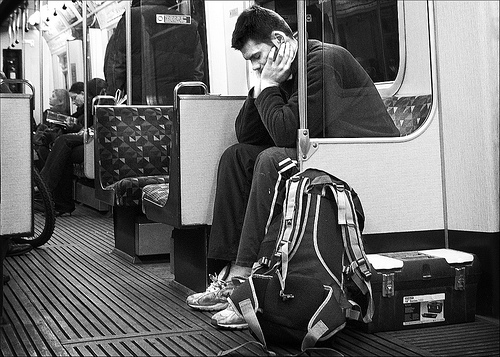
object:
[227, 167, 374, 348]
bag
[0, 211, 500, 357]
floor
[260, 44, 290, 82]
hand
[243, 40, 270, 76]
face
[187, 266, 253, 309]
feet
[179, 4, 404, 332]
man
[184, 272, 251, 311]
shoe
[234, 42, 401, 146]
shirt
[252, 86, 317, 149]
sleeve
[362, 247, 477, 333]
case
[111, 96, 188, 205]
seat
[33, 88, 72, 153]
people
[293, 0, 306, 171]
pole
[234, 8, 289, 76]
head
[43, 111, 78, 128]
magazine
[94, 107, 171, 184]
back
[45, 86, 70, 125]
woman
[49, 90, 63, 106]
head